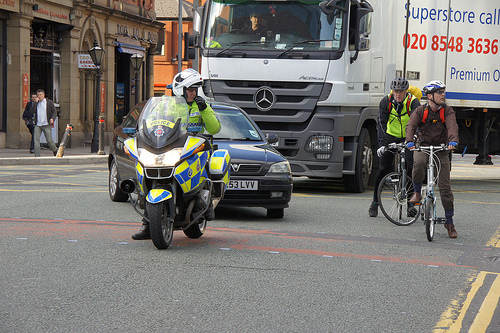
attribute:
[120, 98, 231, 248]
motorcycle — blue, yellow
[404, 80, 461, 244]
person — riding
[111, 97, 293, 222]
car — black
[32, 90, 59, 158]
person — walking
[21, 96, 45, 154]
person — walking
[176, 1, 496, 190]
truck — white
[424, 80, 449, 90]
helmet — blue, white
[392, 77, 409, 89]
helmet — black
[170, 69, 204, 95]
helmet — white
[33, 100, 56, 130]
shirt — white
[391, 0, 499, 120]
box — white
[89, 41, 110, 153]
pole — black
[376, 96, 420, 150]
jacket — yellow, black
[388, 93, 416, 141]
vest — yellow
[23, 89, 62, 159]
people — walking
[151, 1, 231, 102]
building — orange